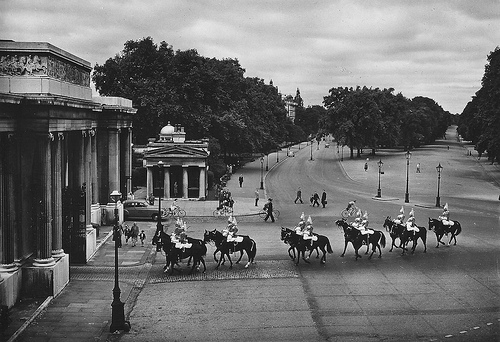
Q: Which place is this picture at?
A: It is at the street.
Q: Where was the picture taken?
A: It was taken at the street.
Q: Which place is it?
A: It is a street.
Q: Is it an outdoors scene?
A: Yes, it is outdoors.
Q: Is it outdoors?
A: Yes, it is outdoors.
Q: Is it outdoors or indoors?
A: It is outdoors.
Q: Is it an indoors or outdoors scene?
A: It is outdoors.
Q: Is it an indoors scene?
A: No, it is outdoors.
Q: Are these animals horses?
A: Yes, all the animals are horses.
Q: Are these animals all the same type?
A: Yes, all the animals are horses.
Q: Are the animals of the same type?
A: Yes, all the animals are horses.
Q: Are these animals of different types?
A: No, all the animals are horses.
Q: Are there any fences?
A: No, there are no fences.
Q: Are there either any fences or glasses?
A: No, there are no fences or glasses.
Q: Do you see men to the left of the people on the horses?
A: Yes, there is a man to the left of the people.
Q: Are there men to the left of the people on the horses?
A: Yes, there is a man to the left of the people.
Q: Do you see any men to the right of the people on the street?
A: No, the man is to the left of the people.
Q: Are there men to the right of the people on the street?
A: No, the man is to the left of the people.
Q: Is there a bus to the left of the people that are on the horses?
A: No, there is a man to the left of the people.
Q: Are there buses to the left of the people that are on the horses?
A: No, there is a man to the left of the people.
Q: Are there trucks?
A: No, there are no trucks.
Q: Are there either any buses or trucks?
A: No, there are no trucks or buses.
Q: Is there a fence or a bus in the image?
A: No, there are no fences or buses.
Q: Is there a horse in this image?
A: Yes, there is a horse.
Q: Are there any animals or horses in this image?
A: Yes, there is a horse.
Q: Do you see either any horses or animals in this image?
A: Yes, there is a horse.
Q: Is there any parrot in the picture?
A: No, there are no parrots.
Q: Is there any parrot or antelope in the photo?
A: No, there are no parrots or antelopes.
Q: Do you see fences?
A: No, there are no fences.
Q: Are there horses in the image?
A: Yes, there is a horse.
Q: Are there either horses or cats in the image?
A: Yes, there is a horse.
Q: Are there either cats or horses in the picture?
A: Yes, there is a horse.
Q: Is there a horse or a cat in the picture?
A: Yes, there is a horse.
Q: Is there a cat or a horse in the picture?
A: Yes, there is a horse.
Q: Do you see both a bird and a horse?
A: No, there is a horse but no birds.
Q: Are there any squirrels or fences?
A: No, there are no fences or squirrels.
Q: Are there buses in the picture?
A: No, there are no buses.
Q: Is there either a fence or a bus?
A: No, there are no buses or fences.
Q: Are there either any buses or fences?
A: No, there are no buses or fences.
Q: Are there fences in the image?
A: No, there are no fences.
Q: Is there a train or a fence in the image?
A: No, there are no fences or trains.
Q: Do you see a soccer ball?
A: No, there are no soccer balls.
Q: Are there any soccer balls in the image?
A: No, there are no soccer balls.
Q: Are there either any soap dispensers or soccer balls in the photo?
A: No, there are no soccer balls or soap dispensers.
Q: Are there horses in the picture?
A: Yes, there are horses.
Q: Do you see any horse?
A: Yes, there are horses.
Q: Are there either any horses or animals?
A: Yes, there are horses.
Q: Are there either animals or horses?
A: Yes, there are horses.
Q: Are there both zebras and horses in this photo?
A: No, there are horses but no zebras.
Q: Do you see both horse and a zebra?
A: No, there are horses but no zebras.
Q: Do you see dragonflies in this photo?
A: No, there are no dragonflies.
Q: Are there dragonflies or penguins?
A: No, there are no dragonflies or penguins.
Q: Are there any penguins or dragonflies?
A: No, there are no dragonflies or penguins.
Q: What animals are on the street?
A: The animals are horses.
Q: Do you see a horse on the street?
A: Yes, there are horses on the street.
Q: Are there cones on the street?
A: No, there are horses on the street.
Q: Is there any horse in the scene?
A: Yes, there is a horse.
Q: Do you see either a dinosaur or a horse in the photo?
A: Yes, there is a horse.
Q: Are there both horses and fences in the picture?
A: No, there is a horse but no fences.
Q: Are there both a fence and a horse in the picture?
A: No, there is a horse but no fences.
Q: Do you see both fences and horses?
A: No, there is a horse but no fences.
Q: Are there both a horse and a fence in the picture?
A: No, there is a horse but no fences.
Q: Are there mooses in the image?
A: No, there are no mooses.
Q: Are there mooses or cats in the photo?
A: No, there are no mooses or cats.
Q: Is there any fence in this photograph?
A: No, there are no fences.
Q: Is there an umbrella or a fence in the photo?
A: No, there are no fences or umbrellas.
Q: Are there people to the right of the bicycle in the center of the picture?
A: Yes, there are people to the right of the bicycle.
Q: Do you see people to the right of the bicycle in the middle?
A: Yes, there are people to the right of the bicycle.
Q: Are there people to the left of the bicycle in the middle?
A: No, the people are to the right of the bicycle.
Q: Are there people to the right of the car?
A: Yes, there are people to the right of the car.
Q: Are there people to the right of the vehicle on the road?
A: Yes, there are people to the right of the car.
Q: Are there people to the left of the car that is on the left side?
A: No, the people are to the right of the car.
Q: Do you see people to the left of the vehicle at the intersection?
A: No, the people are to the right of the car.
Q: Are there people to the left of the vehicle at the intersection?
A: No, the people are to the right of the car.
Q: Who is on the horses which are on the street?
A: The people are on the horses.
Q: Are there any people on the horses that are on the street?
A: Yes, there are people on the horses.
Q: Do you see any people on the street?
A: Yes, there are people on the street.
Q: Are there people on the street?
A: Yes, there are people on the street.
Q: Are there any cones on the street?
A: No, there are people on the street.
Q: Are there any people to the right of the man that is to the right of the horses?
A: Yes, there are people to the right of the man.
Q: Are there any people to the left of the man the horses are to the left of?
A: No, the people are to the right of the man.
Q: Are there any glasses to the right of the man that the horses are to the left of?
A: No, there are people to the right of the man.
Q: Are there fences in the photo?
A: No, there are no fences.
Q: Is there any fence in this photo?
A: No, there are no fences.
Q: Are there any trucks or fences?
A: No, there are no fences or trucks.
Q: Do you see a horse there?
A: Yes, there is a horse.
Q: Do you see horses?
A: Yes, there is a horse.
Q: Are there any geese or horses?
A: Yes, there is a horse.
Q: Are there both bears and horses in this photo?
A: No, there is a horse but no bears.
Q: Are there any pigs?
A: No, there are no pigs.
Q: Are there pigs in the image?
A: No, there are no pigs.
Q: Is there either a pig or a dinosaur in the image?
A: No, there are no pigs or dinosaurs.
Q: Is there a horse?
A: Yes, there is a horse.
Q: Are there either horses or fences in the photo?
A: Yes, there is a horse.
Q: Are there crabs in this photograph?
A: No, there are no crabs.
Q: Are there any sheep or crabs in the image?
A: No, there are no crabs or sheep.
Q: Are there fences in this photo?
A: No, there are no fences.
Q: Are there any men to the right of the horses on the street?
A: Yes, there is a man to the right of the horses.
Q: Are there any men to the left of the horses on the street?
A: No, the man is to the right of the horses.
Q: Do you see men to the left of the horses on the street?
A: No, the man is to the right of the horses.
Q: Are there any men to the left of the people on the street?
A: Yes, there is a man to the left of the people.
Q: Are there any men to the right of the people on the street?
A: No, the man is to the left of the people.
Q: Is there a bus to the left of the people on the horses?
A: No, there is a man to the left of the people.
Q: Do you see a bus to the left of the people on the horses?
A: No, there is a man to the left of the people.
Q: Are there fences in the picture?
A: No, there are no fences.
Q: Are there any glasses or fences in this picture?
A: No, there are no fences or glasses.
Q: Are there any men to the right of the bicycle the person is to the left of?
A: Yes, there is a man to the right of the bicycle.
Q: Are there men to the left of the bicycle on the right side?
A: No, the man is to the right of the bicycle.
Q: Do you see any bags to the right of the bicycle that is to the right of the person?
A: No, there is a man to the right of the bicycle.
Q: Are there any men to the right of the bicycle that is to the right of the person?
A: Yes, there is a man to the right of the bicycle.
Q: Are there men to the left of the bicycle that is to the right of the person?
A: No, the man is to the right of the bicycle.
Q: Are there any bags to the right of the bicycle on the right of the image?
A: No, there is a man to the right of the bicycle.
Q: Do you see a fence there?
A: No, there are no fences.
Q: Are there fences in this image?
A: No, there are no fences.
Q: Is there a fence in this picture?
A: No, there are no fences.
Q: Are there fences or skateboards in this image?
A: No, there are no fences or skateboards.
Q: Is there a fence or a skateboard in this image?
A: No, there are no fences or skateboards.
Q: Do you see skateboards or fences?
A: No, there are no fences or skateboards.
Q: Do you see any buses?
A: No, there are no buses.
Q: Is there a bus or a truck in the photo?
A: No, there are no buses or trucks.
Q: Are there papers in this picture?
A: No, there are no papers.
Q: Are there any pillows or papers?
A: No, there are no papers or pillows.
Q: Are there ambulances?
A: No, there are no ambulances.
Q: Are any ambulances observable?
A: No, there are no ambulances.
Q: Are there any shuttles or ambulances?
A: No, there are no ambulances or shuttles.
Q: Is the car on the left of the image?
A: Yes, the car is on the left of the image.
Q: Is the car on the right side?
A: No, the car is on the left of the image.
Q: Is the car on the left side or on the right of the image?
A: The car is on the left of the image.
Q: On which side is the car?
A: The car is on the left of the image.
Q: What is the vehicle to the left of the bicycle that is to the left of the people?
A: The vehicle is a car.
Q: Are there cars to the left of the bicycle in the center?
A: Yes, there is a car to the left of the bicycle.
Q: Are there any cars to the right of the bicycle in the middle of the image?
A: No, the car is to the left of the bicycle.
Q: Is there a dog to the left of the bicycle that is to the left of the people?
A: No, there is a car to the left of the bicycle.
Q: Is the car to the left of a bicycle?
A: Yes, the car is to the left of a bicycle.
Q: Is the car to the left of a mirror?
A: No, the car is to the left of a bicycle.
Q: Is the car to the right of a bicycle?
A: No, the car is to the left of a bicycle.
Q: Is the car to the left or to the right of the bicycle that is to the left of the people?
A: The car is to the left of the bicycle.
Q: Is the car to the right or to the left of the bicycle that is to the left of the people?
A: The car is to the left of the bicycle.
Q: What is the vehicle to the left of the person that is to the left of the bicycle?
A: The vehicle is a car.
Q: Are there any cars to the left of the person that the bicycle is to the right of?
A: Yes, there is a car to the left of the person.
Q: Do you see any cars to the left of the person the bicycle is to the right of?
A: Yes, there is a car to the left of the person.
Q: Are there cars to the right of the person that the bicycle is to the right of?
A: No, the car is to the left of the person.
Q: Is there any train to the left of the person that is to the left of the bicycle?
A: No, there is a car to the left of the person.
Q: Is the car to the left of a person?
A: Yes, the car is to the left of a person.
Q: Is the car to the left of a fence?
A: No, the car is to the left of a person.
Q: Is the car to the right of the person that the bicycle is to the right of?
A: No, the car is to the left of the person.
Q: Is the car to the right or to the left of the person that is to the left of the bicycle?
A: The car is to the left of the person.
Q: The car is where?
A: The car is at the intersection.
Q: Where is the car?
A: The car is at the intersection.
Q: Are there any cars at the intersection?
A: Yes, there is a car at the intersection.